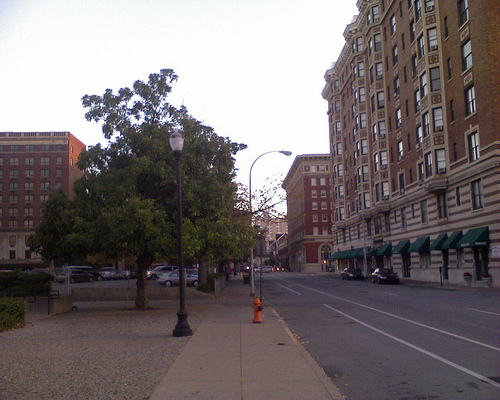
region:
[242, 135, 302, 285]
a street light on side walk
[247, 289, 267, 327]
a red fire hydrant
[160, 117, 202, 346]
a street pole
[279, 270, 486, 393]
white lines in middle of road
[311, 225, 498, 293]
green awnings on a building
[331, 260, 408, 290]
two cars parking in front a building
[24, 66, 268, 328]
a tree behind a street light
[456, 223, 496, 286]
awning above a door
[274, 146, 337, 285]
a red building on a corner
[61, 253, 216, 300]
cars parked in a parking lot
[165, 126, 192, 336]
The dark central street light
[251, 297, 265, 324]
An orange water hydrant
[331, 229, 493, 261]
The green awnings on the building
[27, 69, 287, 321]
A huge tree in the street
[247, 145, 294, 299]
The curved street light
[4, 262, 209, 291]
Several cars in the parking lot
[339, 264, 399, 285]
Two cars parked next to the building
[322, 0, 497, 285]
The high storeyed building with awnings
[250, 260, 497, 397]
A tarmacked road in a street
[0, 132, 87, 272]
The brown tall building on the left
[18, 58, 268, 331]
large tree on side of street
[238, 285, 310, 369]
orange and black fire hydrant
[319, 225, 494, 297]
green awnings on building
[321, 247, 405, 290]
2 cars parallel parked outside large building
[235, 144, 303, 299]
street light with curve at top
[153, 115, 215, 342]
black iron decorative street light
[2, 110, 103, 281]
highrise building with red brick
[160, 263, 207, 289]
silver car parked in background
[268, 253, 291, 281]
car with headlights on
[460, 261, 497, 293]
2 pots of red flowers outside door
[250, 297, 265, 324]
A red fire hydrant.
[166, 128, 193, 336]
A lamp post along the sidewalk.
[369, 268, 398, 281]
A black car parked along the street.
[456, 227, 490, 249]
A green awning with white writing on it.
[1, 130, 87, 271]
A red brick building on the left.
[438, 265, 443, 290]
A vacant parking place with parking meter.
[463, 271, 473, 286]
A cement planter.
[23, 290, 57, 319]
A stairwell going downwards.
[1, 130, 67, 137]
Large writing on the top side of a building.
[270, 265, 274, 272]
A red tail light in use.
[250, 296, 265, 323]
an orange fire hydrant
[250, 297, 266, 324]
an orange fire hydrant on the sidewalk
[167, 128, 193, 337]
a lamp on a black light pole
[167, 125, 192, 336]
a light pole on the sidewalk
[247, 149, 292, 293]
a street lamp on a pole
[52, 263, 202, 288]
automobiles in a parking lot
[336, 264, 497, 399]
two cars parked on the side of the street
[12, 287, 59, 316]
two handrails to the steps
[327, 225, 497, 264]
green exterior window shades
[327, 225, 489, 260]
green shades over the windows